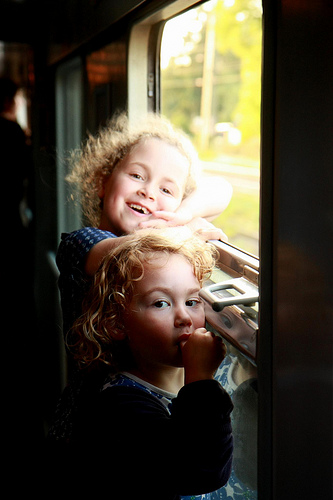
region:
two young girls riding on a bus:
[51, 121, 265, 496]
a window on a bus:
[156, 20, 251, 252]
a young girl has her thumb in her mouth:
[172, 328, 230, 377]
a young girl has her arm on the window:
[148, 128, 241, 233]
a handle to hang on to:
[199, 270, 261, 312]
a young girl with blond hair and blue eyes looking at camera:
[63, 217, 235, 499]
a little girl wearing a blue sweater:
[87, 367, 237, 489]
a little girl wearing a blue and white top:
[88, 370, 248, 494]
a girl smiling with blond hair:
[74, 117, 233, 227]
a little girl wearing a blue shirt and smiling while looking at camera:
[61, 113, 242, 229]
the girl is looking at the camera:
[111, 242, 218, 350]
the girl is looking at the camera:
[116, 250, 291, 427]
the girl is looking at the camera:
[93, 189, 244, 463]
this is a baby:
[128, 233, 215, 412]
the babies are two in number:
[89, 123, 198, 486]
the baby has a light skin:
[145, 317, 171, 338]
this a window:
[199, 71, 251, 194]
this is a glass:
[200, 22, 239, 109]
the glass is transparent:
[204, 45, 251, 109]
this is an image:
[216, 312, 246, 337]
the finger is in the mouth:
[178, 327, 215, 365]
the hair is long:
[95, 274, 112, 327]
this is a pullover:
[157, 423, 217, 465]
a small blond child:
[76, 234, 232, 497]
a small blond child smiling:
[55, 107, 218, 496]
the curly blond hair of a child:
[66, 112, 196, 223]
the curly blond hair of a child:
[67, 237, 216, 371]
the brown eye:
[128, 170, 143, 182]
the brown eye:
[160, 186, 172, 194]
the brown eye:
[151, 298, 170, 309]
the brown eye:
[186, 297, 202, 306]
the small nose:
[173, 307, 192, 325]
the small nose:
[135, 176, 157, 200]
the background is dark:
[3, 318, 34, 354]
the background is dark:
[25, 360, 83, 434]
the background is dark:
[14, 326, 111, 445]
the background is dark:
[17, 328, 69, 406]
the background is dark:
[33, 341, 100, 424]